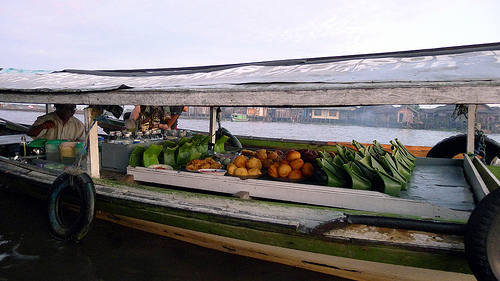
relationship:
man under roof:
[27, 104, 86, 167] [0, 53, 498, 110]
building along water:
[303, 107, 356, 122] [305, 116, 375, 153]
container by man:
[45, 139, 71, 163] [26, 96, 89, 141]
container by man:
[59, 142, 86, 165] [26, 96, 89, 141]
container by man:
[74, 142, 86, 163] [26, 96, 89, 141]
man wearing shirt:
[27, 104, 86, 167] [32, 112, 87, 153]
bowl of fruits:
[197, 163, 229, 175] [269, 145, 310, 179]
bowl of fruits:
[224, 167, 260, 178] [228, 149, 265, 177]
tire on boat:
[457, 175, 499, 280] [0, 38, 490, 279]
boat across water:
[224, 110, 251, 127] [180, 117, 465, 146]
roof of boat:
[0, 82, 498, 111] [0, 38, 490, 279]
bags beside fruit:
[321, 139, 417, 196] [186, 147, 316, 180]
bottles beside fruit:
[104, 126, 185, 171] [189, 144, 305, 182]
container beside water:
[45, 139, 71, 163] [1, 102, 496, 164]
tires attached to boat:
[50, 130, 499, 277] [10, 71, 484, 276]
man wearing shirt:
[26, 95, 100, 168] [30, 104, 87, 141]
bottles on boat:
[110, 127, 125, 148] [29, 89, 370, 248]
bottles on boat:
[129, 127, 145, 141] [29, 89, 370, 248]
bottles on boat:
[151, 127, 167, 144] [29, 89, 370, 248]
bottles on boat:
[155, 125, 174, 137] [29, 89, 370, 248]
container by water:
[59, 141, 79, 165] [3, 106, 499, 158]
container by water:
[43, 138, 62, 169] [3, 106, 499, 158]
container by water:
[77, 139, 87, 172] [3, 106, 499, 158]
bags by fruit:
[318, 137, 416, 194] [186, 147, 316, 180]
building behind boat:
[384, 100, 419, 130] [0, 38, 490, 279]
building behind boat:
[427, 103, 452, 130] [0, 38, 490, 279]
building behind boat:
[308, 102, 341, 124] [0, 38, 490, 279]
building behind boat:
[255, 104, 296, 126] [0, 38, 490, 279]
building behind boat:
[347, 106, 394, 123] [0, 38, 490, 279]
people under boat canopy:
[87, 99, 197, 149] [0, 42, 499, 106]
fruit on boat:
[183, 140, 315, 185] [0, 38, 490, 279]